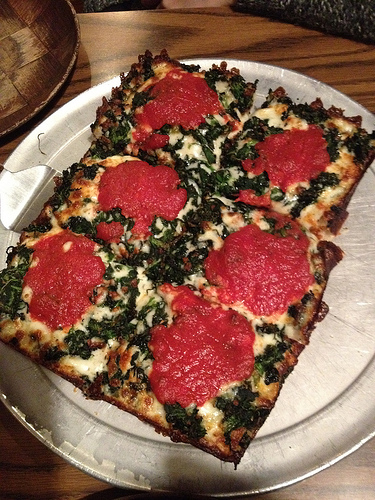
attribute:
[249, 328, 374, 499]
tray — gray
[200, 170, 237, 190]
basil — crushed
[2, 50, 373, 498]
plate — silver, grey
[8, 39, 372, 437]
plate — metal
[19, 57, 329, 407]
sauce — red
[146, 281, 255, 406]
sauce — tomato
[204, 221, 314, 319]
sauce — red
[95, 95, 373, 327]
pizza — slice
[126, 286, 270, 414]
sauce — red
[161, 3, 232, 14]
hand — white, of a person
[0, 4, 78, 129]
bowl — wooden, empty, round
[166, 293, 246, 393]
sauce — red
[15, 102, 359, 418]
pizza — just baked, rectangular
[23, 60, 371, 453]
pizza — slice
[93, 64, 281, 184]
pizza — slice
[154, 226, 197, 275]
basil — green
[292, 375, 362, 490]
baking pan — round, silver